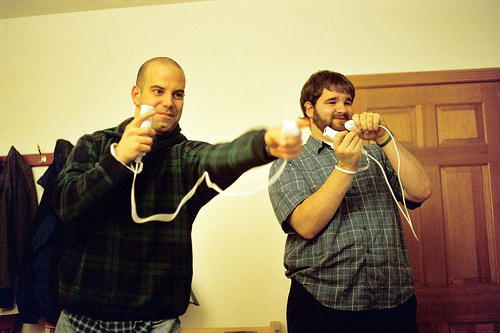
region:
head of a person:
[289, 57, 359, 134]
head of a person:
[122, 50, 194, 136]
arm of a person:
[195, 118, 314, 185]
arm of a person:
[56, 128, 136, 225]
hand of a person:
[123, 108, 163, 150]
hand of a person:
[263, 117, 315, 167]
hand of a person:
[325, 128, 371, 170]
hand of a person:
[348, 103, 391, 141]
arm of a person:
[293, 171, 363, 227]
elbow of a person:
[400, 153, 440, 204]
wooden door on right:
[404, 84, 490, 313]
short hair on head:
[134, 60, 192, 91]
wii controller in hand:
[267, 116, 299, 146]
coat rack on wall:
[5, 138, 67, 170]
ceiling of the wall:
[37, 6, 85, 25]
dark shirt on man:
[97, 230, 164, 290]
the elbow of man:
[277, 200, 348, 238]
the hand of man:
[343, 109, 376, 129]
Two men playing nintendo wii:
[40, 53, 433, 325]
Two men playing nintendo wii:
[47, 53, 433, 328]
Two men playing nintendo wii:
[52, 55, 437, 331]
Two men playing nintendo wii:
[52, 52, 433, 327]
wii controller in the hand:
[318, 126, 366, 167]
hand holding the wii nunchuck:
[341, 108, 391, 138]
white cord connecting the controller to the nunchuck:
[322, 116, 433, 253]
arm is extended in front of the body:
[171, 123, 312, 204]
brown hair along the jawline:
[308, 102, 354, 138]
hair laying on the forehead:
[327, 82, 357, 96]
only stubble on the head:
[123, 49, 188, 93]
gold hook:
[31, 141, 51, 164]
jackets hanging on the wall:
[0, 135, 83, 324]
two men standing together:
[47, 22, 452, 319]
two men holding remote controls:
[49, 25, 458, 314]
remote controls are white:
[109, 90, 440, 271]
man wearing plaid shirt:
[272, 128, 427, 313]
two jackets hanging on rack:
[0, 128, 90, 329]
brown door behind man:
[297, 46, 495, 328]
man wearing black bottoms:
[281, 244, 430, 331]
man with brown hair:
[284, 56, 361, 114]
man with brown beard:
[304, 106, 360, 135]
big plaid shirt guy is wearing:
[261, 123, 429, 310]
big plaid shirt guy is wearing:
[252, 120, 434, 306]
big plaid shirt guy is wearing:
[253, 126, 428, 309]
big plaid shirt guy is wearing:
[252, 118, 430, 310]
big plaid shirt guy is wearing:
[256, 122, 423, 312]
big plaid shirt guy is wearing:
[244, 122, 434, 306]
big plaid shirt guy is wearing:
[254, 118, 430, 317]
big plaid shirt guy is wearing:
[257, 118, 422, 313]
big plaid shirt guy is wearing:
[256, 120, 436, 316]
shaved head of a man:
[133, 54, 185, 91]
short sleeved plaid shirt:
[265, 133, 420, 309]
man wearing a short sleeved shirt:
[267, 64, 434, 331]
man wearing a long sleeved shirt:
[43, 50, 306, 327]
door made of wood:
[322, 65, 499, 329]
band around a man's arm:
[376, 127, 395, 154]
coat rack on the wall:
[3, 146, 68, 170]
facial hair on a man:
[313, 108, 355, 134]